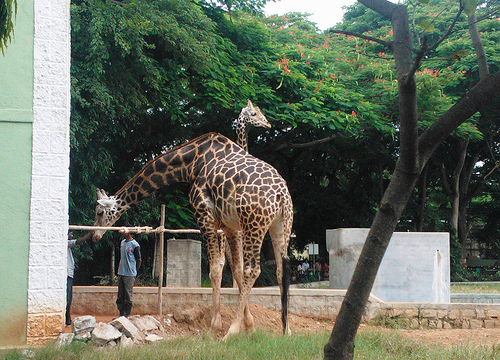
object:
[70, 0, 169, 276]
trees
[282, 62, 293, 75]
flowers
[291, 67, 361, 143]
tree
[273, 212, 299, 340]
giraffe legs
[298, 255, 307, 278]
people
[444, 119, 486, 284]
tree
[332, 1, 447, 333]
trunk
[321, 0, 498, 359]
trees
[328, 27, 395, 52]
branches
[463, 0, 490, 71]
branches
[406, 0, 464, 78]
branches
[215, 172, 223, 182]
pattern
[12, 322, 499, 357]
grass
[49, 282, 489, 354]
ground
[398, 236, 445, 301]
wall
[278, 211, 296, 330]
tail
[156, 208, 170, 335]
pillar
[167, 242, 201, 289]
bricks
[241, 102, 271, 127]
head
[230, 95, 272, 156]
giraffe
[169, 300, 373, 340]
dirt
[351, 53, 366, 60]
flower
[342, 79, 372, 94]
flower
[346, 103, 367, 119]
flower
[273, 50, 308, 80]
flower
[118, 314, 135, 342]
rocks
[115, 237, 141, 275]
blue shirt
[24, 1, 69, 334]
stone wall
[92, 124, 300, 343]
giraffe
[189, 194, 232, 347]
legs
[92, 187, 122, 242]
head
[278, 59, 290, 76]
flower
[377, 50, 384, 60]
flower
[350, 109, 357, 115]
flower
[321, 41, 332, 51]
flower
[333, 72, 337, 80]
flower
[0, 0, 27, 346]
wall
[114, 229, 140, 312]
boy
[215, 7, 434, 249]
tree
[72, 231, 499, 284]
fence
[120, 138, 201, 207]
neck